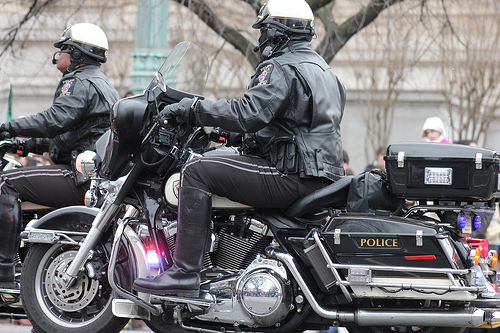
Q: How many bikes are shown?
A: Two.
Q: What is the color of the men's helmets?
A: White.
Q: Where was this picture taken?
A: The street.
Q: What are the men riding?
A: Motorcycles.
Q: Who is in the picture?
A: Two men.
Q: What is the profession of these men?
A: They are police officers.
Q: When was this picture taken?
A: Daytime.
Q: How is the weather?
A: Overcast.